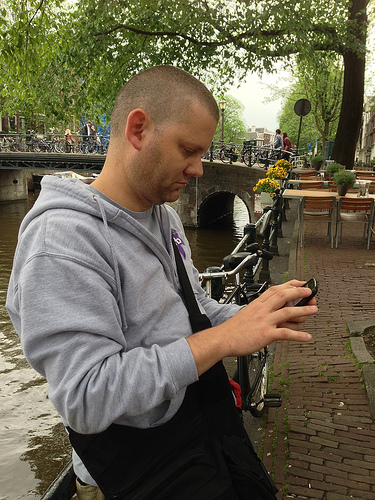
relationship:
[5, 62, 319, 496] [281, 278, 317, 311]
man looking at phone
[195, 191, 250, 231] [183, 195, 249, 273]
arch over water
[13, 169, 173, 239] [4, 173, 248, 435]
hood on back of sweatshirt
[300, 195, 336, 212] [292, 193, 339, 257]
back of chair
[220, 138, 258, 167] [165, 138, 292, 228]
bike on bridge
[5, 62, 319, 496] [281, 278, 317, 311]
man using phone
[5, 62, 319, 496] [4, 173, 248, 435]
man wearing sweatshirt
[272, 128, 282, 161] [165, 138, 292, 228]
person walking on bridge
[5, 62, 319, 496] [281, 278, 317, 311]
man holding phone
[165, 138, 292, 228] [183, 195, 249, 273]
bridge over water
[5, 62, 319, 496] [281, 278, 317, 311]
man on phone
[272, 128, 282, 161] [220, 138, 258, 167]
person riding bike